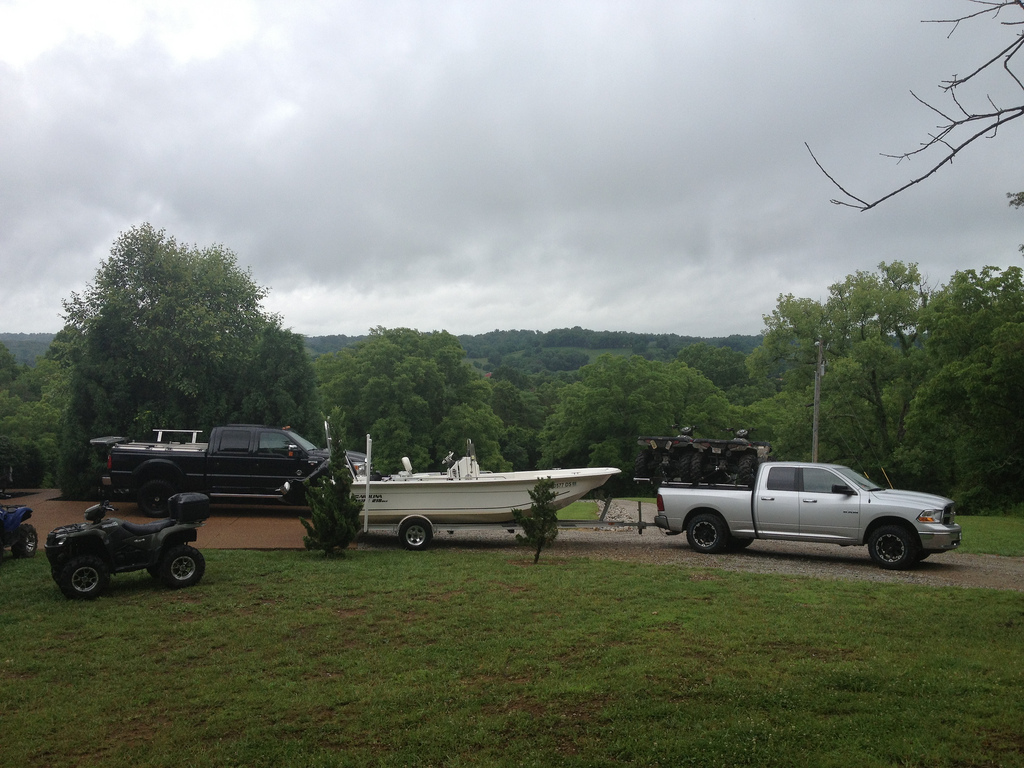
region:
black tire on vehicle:
[862, 519, 924, 573]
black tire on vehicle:
[682, 508, 724, 556]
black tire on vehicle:
[720, 534, 756, 553]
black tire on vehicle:
[149, 540, 207, 592]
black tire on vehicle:
[15, 521, 39, 556]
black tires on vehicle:
[685, 516, 924, 567]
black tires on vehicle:
[57, 546, 207, 603]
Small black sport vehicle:
[47, 493, 240, 599]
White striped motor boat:
[322, 455, 630, 545]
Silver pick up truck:
[659, 447, 967, 568]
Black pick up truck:
[90, 417, 378, 512]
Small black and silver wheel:
[399, 509, 439, 551]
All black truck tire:
[684, 507, 730, 556]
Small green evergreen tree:
[511, 477, 576, 566]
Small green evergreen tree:
[279, 418, 372, 559]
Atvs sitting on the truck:
[637, 412, 774, 492]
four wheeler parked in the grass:
[47, 499, 207, 637]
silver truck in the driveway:
[625, 443, 964, 595]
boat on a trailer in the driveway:
[343, 449, 607, 545]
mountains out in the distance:
[290, 316, 699, 449]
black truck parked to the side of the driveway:
[106, 427, 351, 508]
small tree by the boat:
[296, 443, 374, 565]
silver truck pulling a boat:
[337, 440, 951, 565]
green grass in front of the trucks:
[216, 593, 754, 753]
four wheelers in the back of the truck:
[630, 417, 764, 490]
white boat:
[362, 435, 628, 540]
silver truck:
[672, 432, 952, 589]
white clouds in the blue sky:
[453, 45, 567, 112]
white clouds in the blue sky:
[506, 250, 605, 340]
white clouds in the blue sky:
[354, 119, 476, 218]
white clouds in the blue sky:
[318, 221, 449, 297]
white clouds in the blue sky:
[503, 25, 628, 177]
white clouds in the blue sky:
[251, 101, 324, 194]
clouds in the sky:
[10, 13, 1014, 328]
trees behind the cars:
[37, 293, 998, 471]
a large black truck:
[97, 437, 323, 508]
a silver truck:
[653, 465, 945, 567]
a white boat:
[309, 476, 605, 537]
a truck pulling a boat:
[326, 454, 933, 571]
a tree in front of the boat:
[299, 433, 360, 539]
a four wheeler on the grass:
[53, 509, 218, 574]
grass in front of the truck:
[16, 552, 1018, 761]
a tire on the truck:
[874, 522, 913, 558]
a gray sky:
[2, 4, 1015, 328]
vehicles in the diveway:
[15, 363, 1022, 620]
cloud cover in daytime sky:
[4, 3, 1022, 335]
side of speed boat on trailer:
[332, 452, 618, 552]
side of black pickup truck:
[101, 423, 361, 512]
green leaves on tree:
[71, 226, 272, 429]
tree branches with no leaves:
[800, 3, 1020, 212]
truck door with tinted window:
[757, 461, 799, 541]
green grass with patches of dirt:
[3, 549, 1018, 762]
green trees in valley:
[0, 328, 1016, 459]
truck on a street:
[648, 441, 993, 578]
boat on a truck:
[340, 430, 644, 566]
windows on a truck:
[759, 460, 846, 508]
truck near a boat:
[71, 416, 329, 497]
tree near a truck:
[43, 209, 344, 425]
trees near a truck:
[759, 252, 1022, 467]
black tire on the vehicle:
[868, 521, 913, 573]